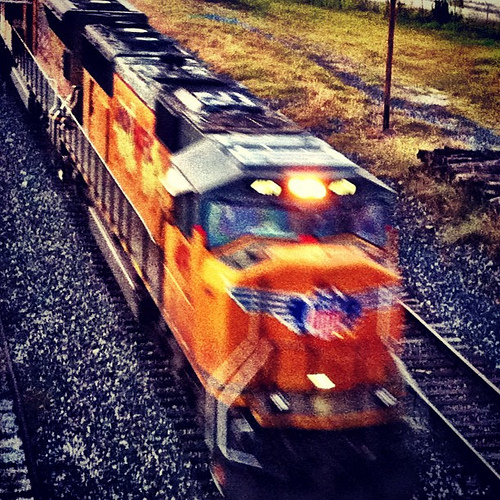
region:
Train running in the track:
[86, 135, 453, 427]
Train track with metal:
[438, 337, 490, 444]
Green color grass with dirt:
[413, 19, 473, 119]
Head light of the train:
[252, 174, 374, 200]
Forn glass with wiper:
[226, 196, 383, 236]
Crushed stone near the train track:
[32, 267, 99, 451]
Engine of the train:
[55, 52, 420, 420]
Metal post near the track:
[378, 13, 413, 128]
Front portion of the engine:
[185, 251, 432, 445]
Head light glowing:
[248, 165, 364, 218]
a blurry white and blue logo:
[227, 285, 399, 339]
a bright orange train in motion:
[0, 4, 412, 484]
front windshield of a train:
[206, 200, 395, 251]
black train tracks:
[410, 311, 497, 498]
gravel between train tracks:
[0, 232, 199, 498]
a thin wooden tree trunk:
[379, 0, 402, 131]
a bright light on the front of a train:
[250, 177, 347, 198]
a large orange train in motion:
[0, 0, 410, 499]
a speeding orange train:
[0, 0, 409, 497]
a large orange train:
[0, 0, 409, 499]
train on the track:
[23, 15, 389, 493]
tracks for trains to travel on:
[440, 349, 485, 444]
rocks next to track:
[21, 291, 149, 469]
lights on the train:
[242, 172, 359, 207]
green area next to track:
[278, 15, 463, 115]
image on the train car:
[223, 282, 397, 299]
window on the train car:
[211, 202, 390, 236]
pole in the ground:
[364, 4, 426, 134]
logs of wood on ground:
[424, 140, 494, 163]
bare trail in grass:
[208, 19, 428, 110]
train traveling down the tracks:
[10, 13, 421, 491]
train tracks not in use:
[405, 304, 499, 466]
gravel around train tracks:
[4, 211, 499, 489]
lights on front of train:
[265, 371, 392, 420]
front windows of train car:
[203, 199, 382, 247]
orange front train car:
[80, 50, 416, 475]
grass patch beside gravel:
[282, 1, 496, 119]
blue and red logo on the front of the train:
[228, 280, 404, 339]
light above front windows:
[285, 176, 329, 201]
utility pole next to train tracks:
[379, 7, 399, 138]